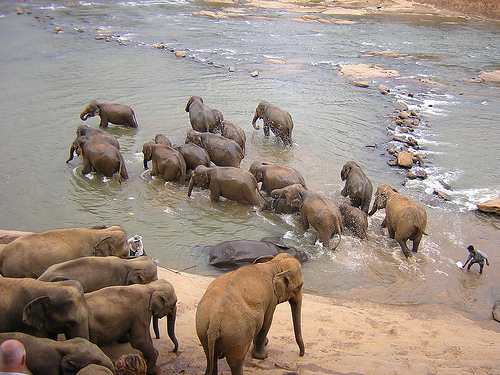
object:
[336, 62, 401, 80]
patch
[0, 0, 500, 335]
water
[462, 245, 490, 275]
man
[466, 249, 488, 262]
shirt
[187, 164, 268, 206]
elephant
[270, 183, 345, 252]
elephant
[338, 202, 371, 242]
elephant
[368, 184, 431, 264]
elephant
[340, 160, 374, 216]
elephant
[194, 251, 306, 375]
elephant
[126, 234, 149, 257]
man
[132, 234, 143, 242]
hat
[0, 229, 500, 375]
shore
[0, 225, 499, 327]
edge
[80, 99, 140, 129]
elephant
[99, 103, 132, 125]
body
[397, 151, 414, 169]
rock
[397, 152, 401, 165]
edge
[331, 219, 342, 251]
tail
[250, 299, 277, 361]
leg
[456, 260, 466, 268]
container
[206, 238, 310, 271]
elephant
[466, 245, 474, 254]
head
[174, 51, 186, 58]
stone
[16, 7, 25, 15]
stone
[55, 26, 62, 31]
stone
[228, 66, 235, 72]
stone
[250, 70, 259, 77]
stone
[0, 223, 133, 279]
elephant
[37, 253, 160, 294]
elephant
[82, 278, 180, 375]
elephant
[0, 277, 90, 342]
elephant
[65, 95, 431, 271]
group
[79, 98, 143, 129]
elephants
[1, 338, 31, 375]
man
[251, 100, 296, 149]
elephant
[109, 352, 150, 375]
person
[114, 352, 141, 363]
top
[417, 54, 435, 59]
object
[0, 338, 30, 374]
head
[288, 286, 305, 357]
trunk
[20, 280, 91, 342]
head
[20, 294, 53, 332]
ear